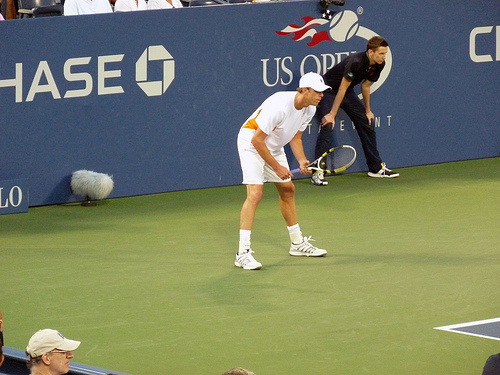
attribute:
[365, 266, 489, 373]
tennis court — white, blue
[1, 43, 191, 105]
chase — ad, logo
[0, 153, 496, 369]
court — green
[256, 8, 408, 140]
logo — US Open, tennis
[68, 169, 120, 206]
bag — Fluffy 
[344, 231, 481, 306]
ground — part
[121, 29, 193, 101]
logo — Chase bank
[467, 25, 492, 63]
letter c — white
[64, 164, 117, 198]
mike — covered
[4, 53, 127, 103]
writing — white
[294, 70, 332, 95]
cap — white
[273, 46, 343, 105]
hat — white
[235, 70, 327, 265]
player — tennis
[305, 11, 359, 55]
ball — white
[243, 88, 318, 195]
outfit — white, tennis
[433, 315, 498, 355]
tennis court — blue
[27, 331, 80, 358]
cap — white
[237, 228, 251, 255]
sock — white, athletic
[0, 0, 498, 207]
wall — blue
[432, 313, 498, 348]
stripe — white